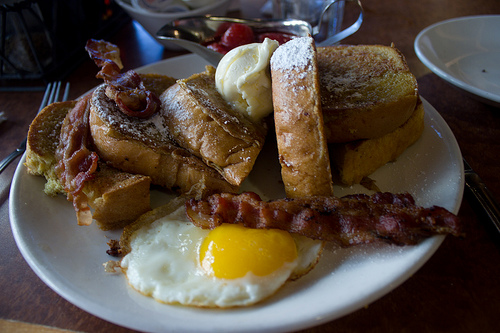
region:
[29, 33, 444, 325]
White circular plate on the table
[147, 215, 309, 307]
Egg cooked sunny side up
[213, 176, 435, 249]
Piece of cooked bacon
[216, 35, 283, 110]
Large serving of butter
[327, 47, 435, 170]
Slices on french toast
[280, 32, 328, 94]
Sugar was poured over french toast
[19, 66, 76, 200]
Silver fork is nect to the plate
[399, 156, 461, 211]
Sugar remains in the plate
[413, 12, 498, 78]
Empty white plate in the background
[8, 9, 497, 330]
Wooden table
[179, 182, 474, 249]
a dlicious strip of bacon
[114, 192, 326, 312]
an egg sunny side up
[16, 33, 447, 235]
six slices of french toast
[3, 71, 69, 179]
a fork next to the plate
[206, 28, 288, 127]
a large dollop of butter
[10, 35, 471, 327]
a breakfast plate full of food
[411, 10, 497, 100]
a small empty plate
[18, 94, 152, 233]
a piece of french toast with bites missing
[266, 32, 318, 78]
powdered sugar on the french toast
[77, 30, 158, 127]
a piece of bacon on a piece of french toast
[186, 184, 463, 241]
a greasy piece of bacon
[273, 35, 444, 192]
three pieces of bread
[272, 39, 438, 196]
French toast with powderedsugar on top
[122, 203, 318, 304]
an over easy egg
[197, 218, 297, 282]
a yellow yolk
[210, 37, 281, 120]
a scoop of butter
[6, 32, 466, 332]
a white plate full of breakfast food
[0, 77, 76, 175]
a silver fork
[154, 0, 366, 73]
a silver bowl filled with cherries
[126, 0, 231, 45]
a little bowl filled with packets of milk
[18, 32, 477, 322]
Breakfast items.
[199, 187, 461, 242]
A red strip of bacon.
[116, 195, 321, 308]
An egg sunny side up.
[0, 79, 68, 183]
A silver fork.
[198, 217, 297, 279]
The yellow yolk of an egg.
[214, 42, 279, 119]
A ball of butter.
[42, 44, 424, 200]
Golden brown french toast.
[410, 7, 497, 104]
An empty white plate.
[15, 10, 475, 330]
A white plate full of food.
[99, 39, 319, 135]
White powdered sugar.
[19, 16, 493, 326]
There are two white plates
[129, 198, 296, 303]
Egg with a yellow yolk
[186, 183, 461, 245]
A red piece of bacon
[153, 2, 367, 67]
The container is silver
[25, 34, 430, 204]
The bread is powdered with sugar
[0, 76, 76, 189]
Fork next to the plate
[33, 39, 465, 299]
French toast with eggs and bacon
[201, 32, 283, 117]
The butter is white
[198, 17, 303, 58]
Red berries in the container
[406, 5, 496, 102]
The plate is empty